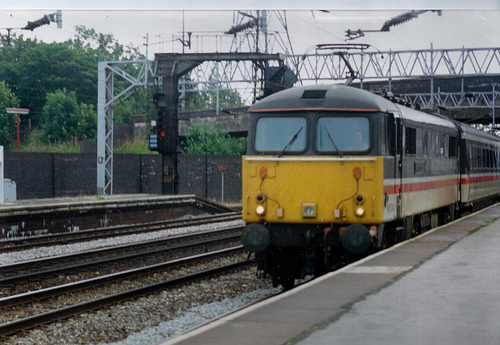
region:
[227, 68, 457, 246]
Large train traveling on tracks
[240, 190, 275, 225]
Headlight on passenger train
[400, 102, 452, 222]
Silver train with black and red stripe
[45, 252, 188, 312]
Train tracks with gravel underneath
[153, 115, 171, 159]
Traffic lights on train track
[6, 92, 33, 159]
Light post at train station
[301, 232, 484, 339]
Platform at train station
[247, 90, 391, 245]
The front of the train is yellow and black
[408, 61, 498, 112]
Bridge to train from parking lot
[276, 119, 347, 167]
Windshield wipers on front of train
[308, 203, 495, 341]
a train platform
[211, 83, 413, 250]
a train with a yellow front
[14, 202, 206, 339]
four sets of train tracks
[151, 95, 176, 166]
a signal light for trains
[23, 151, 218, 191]
a rock wall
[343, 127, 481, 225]
a red stripe on a train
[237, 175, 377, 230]
lights on the front of a train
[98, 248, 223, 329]
gravel between the train tracks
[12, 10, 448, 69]
electrical wires and cables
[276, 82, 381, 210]
a man driving a train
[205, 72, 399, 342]
train in the train tracks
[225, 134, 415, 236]
the front of train is yellow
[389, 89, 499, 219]
train cars is stripes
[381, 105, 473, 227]
train cars are red, white and black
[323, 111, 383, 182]
a train driver in the front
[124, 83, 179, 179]
traffic light attached to a bar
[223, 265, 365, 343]
white lines on the ground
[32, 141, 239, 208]
the fence is brown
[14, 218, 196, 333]
the train tracks have small rocks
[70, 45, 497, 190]
the bars are silver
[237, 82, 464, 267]
the engine of the train is yellow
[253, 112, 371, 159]
the windows of the have windshield wipers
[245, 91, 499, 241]
the engine is pulling a passenger car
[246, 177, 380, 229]
the lights are on the front of the train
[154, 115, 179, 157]
a red light is next to the tracks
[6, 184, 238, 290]
a platform is next to the tracks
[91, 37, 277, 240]
steel towers are by the tracks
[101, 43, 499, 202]
steel scaffolding is over the tracks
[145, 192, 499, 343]
the train is near a platform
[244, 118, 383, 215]
the engineer is sitting in the engine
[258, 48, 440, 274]
A train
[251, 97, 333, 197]
A train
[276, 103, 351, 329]
A train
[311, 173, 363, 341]
A train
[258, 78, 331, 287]
A train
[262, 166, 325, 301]
A train